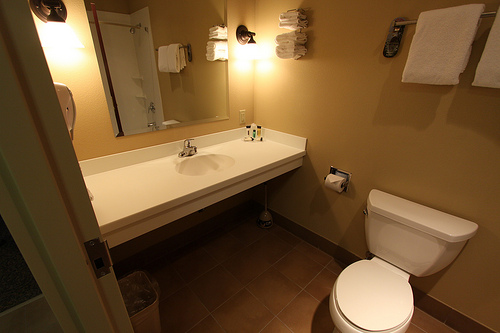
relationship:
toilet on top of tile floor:
[328, 187, 479, 332] [117, 211, 462, 332]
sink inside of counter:
[175, 151, 234, 175] [79, 121, 308, 248]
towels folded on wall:
[274, 8, 309, 60] [251, 0, 497, 332]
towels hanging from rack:
[399, 4, 499, 91] [392, 9, 497, 28]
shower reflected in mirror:
[87, 3, 167, 139] [84, 1, 230, 137]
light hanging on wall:
[236, 22, 259, 58] [29, 1, 255, 280]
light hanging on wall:
[30, 0, 80, 59] [29, 1, 255, 280]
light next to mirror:
[236, 22, 259, 58] [84, 1, 230, 137]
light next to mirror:
[30, 0, 80, 59] [84, 1, 230, 137]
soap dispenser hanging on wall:
[53, 81, 77, 144] [2, 0, 136, 333]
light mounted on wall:
[236, 22, 259, 58] [29, 1, 255, 280]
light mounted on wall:
[30, 0, 80, 59] [29, 1, 255, 280]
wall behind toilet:
[251, 0, 497, 332] [328, 187, 479, 332]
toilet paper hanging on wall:
[323, 174, 346, 194] [251, 0, 497, 332]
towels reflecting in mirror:
[156, 41, 186, 75] [84, 1, 230, 137]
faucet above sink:
[177, 136, 198, 158] [175, 151, 234, 175]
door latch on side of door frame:
[82, 233, 113, 279] [1, 0, 137, 332]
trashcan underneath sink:
[118, 266, 162, 331] [175, 151, 234, 175]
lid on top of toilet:
[337, 258, 414, 333] [328, 187, 479, 332]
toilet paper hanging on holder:
[323, 174, 346, 194] [323, 165, 352, 195]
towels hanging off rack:
[399, 4, 486, 88] [392, 9, 497, 28]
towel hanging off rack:
[471, 6, 499, 90] [392, 9, 497, 28]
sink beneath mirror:
[175, 151, 234, 175] [84, 1, 230, 137]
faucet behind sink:
[177, 136, 198, 158] [175, 151, 234, 175]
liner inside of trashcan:
[116, 265, 161, 326] [118, 266, 162, 331]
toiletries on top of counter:
[242, 121, 264, 143] [79, 121, 308, 248]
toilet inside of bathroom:
[328, 187, 479, 332] [0, 0, 499, 332]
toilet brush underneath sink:
[257, 180, 274, 229] [175, 151, 234, 175]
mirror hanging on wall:
[84, 1, 230, 137] [29, 1, 255, 280]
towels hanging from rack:
[399, 4, 486, 88] [392, 9, 497, 28]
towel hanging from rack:
[471, 6, 499, 90] [392, 9, 497, 28]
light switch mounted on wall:
[238, 109, 246, 126] [29, 1, 255, 280]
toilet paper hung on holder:
[323, 174, 346, 194] [323, 165, 352, 195]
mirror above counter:
[84, 1, 230, 137] [79, 121, 308, 248]